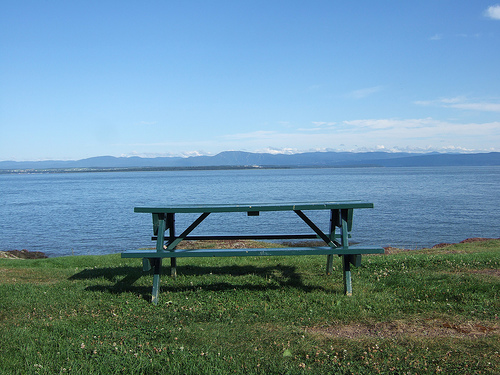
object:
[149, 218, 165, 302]
leg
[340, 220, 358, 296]
leg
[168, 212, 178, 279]
leg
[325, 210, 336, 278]
leg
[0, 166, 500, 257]
water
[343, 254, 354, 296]
feet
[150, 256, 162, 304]
feet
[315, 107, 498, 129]
cloud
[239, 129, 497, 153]
cloud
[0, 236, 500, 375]
ground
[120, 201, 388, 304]
bench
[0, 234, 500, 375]
grass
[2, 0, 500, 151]
sky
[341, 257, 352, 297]
leg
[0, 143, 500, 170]
mountain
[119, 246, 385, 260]
seat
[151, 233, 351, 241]
seat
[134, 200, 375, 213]
top